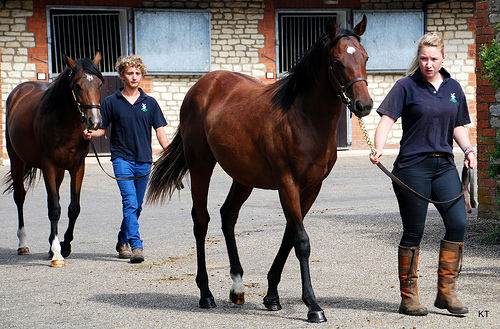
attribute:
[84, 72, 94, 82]
spot — white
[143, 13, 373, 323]
horse — brown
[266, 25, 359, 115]
mane — black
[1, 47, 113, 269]
horse — brown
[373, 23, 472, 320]
girl — blonde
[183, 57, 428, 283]
horses — brown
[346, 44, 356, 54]
spot — is white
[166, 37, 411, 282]
horse — brown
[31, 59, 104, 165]
mane — dark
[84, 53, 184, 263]
boy — young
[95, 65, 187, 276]
boy — young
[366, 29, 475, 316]
girl — sexy, blonde